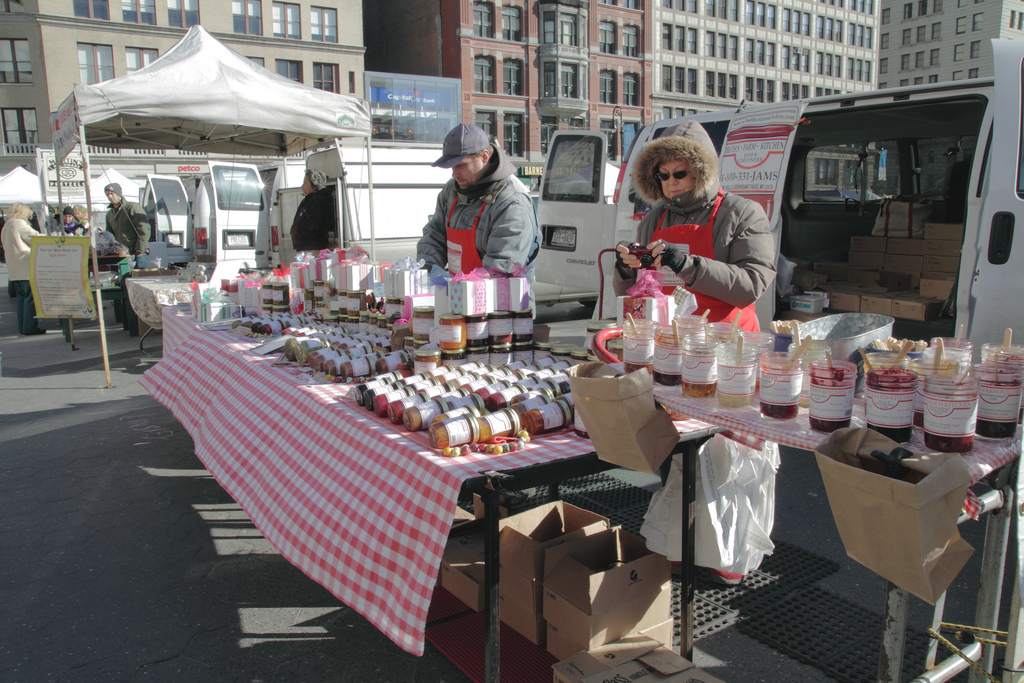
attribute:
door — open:
[205, 160, 273, 288]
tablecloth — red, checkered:
[134, 299, 720, 656]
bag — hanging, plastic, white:
[640, 431, 747, 570]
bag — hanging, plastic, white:
[730, 437, 756, 580]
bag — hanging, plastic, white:
[730, 487, 776, 585]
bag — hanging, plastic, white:
[760, 435, 784, 542]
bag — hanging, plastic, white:
[754, 452, 770, 530]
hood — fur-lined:
[626, 115, 728, 209]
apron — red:
[648, 186, 761, 344]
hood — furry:
[621, 117, 723, 213]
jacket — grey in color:
[610, 115, 773, 316]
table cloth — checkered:
[141, 305, 645, 668]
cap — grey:
[427, 116, 510, 171]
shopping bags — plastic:
[632, 433, 786, 589]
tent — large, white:
[42, 14, 382, 397]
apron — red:
[637, 182, 759, 338]